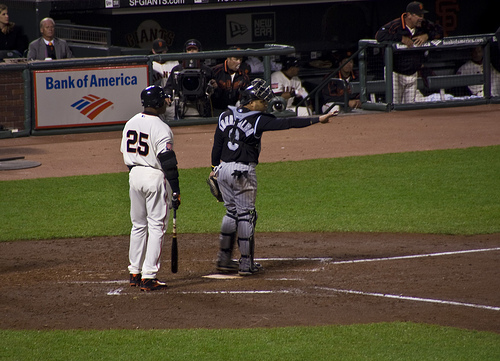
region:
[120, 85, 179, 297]
Barry Bonds standing in batters box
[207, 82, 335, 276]
Colorado Rockies catcher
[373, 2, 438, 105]
Giants manager Bochy leaning on dugout rail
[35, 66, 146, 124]
Bank of America advertisment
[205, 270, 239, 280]
home plate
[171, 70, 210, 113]
television camera in camera well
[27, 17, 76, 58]
fan in a gray suit in front row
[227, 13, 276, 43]
New Era cap ad in dugout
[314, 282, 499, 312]
first base line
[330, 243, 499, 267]
third base line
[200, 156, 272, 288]
grey and black striped pants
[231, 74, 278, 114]
catcher's mask and helmet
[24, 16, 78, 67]
man wearing a grey suit jacket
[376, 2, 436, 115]
man wearing white pants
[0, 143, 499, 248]
strip of lush green grass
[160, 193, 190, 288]
black and white base ball bat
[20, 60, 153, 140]
red, white, and blue bank of america advert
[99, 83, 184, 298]
man wearing a white base ball uniform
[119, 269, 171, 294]
pair of black and orange cleats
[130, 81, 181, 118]
shiny black plastic base ball helmet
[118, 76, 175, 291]
a tall person standing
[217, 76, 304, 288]
a black person standing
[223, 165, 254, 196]
a small object on pant pocket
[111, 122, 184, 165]
a number displayed on back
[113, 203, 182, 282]
two legs of the person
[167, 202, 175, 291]
a small object holding by a person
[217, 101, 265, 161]
a small text written on back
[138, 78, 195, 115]
a small cap wearing by person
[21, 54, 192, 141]
a small board of advertisement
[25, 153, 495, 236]
a beautiful green grass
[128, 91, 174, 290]
this is a man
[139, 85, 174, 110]
this is the helmet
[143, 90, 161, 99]
the helmet is black in color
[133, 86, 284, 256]
the are two men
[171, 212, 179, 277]
this is a bat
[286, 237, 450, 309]
this is a bare ground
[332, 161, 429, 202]
this is a grass area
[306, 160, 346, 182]
the grass is green in color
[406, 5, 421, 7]
this is a cap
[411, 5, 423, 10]
the cap is black in color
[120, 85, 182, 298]
baseball player in white uniform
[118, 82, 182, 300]
baseball player holding a black bat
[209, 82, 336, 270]
catcher with right arm extended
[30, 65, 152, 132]
white sign with red border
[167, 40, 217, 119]
cameraman filming a baseball game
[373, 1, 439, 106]
man leaning on fence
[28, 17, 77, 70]
man wearing grey suit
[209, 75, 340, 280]
baseball player in black shirt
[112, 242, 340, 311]
batter's box markings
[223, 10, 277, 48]
sign advertising sports wear